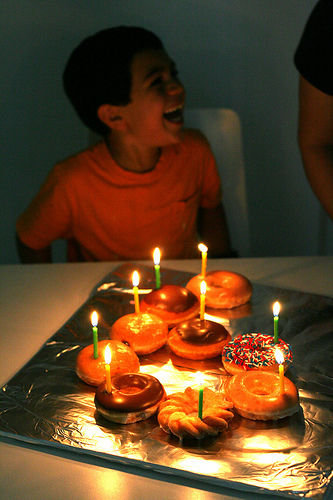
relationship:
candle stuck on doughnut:
[278, 360, 286, 396] [224, 369, 299, 420]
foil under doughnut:
[2, 262, 331, 499] [224, 369, 299, 420]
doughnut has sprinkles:
[221, 332, 292, 374] [219, 332, 292, 372]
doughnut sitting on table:
[224, 369, 299, 420] [1, 253, 333, 500]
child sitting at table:
[13, 22, 238, 263] [1, 253, 333, 500]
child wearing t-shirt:
[13, 22, 238, 263] [12, 127, 225, 263]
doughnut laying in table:
[224, 369, 299, 420] [1, 253, 333, 500]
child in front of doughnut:
[13, 22, 238, 263] [224, 369, 299, 420]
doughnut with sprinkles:
[221, 332, 292, 374] [219, 332, 292, 372]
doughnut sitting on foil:
[224, 369, 299, 420] [2, 262, 331, 499]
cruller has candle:
[157, 385, 233, 439] [197, 371, 205, 418]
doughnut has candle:
[224, 369, 299, 420] [278, 360, 286, 396]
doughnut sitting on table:
[109, 312, 167, 355] [1, 253, 333, 500]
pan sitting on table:
[0, 262, 332, 497] [1, 253, 333, 500]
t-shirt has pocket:
[12, 127, 225, 263] [171, 188, 200, 246]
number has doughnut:
[75, 268, 301, 441] [224, 369, 299, 420]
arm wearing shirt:
[291, 0, 332, 220] [289, 0, 331, 95]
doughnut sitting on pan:
[221, 332, 292, 374] [0, 262, 332, 497]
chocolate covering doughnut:
[176, 319, 228, 346] [165, 317, 231, 359]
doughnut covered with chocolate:
[165, 317, 231, 359] [176, 319, 228, 346]